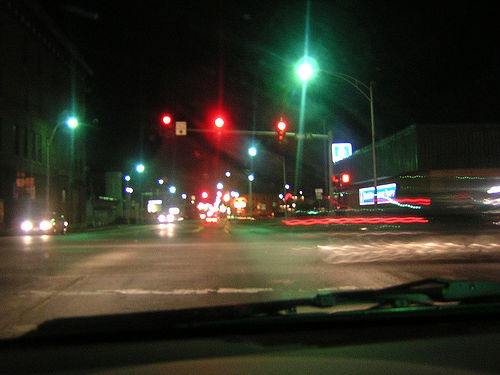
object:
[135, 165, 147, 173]
street light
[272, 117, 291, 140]
light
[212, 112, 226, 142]
light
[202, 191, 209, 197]
light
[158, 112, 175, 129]
left traffic light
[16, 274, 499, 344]
rain wiper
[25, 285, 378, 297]
traffic line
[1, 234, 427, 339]
intersection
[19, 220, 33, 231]
headlights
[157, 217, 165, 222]
headlights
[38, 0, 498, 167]
sky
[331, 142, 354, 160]
lit sign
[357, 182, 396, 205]
wall sign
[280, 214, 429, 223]
brake light streak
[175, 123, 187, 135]
traffic sign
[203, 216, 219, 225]
tail lights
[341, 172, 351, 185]
pedestrian light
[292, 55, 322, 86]
street light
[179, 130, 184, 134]
crossbar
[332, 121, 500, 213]
building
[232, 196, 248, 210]
neon sign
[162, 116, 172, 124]
circle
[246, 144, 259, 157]
second street light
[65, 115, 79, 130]
street light